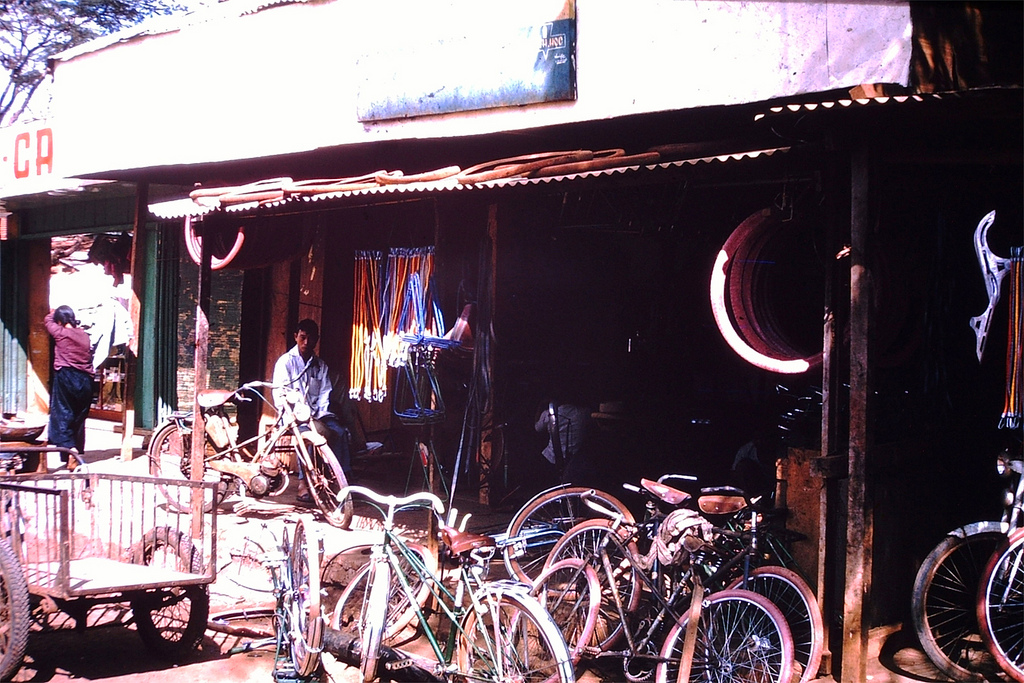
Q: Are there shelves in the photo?
A: No, there are no shelves.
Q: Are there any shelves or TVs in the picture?
A: No, there are no shelves or tvs.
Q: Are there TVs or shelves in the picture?
A: No, there are no shelves or tvs.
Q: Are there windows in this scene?
A: Yes, there is a window.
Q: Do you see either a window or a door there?
A: Yes, there is a window.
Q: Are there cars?
A: No, there are no cars.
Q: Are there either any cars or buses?
A: No, there are no cars or buses.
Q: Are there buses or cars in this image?
A: No, there are no cars or buses.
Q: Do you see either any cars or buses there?
A: No, there are no cars or buses.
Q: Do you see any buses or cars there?
A: No, there are no cars or buses.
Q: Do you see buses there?
A: No, there are no buses.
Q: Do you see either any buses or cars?
A: No, there are no buses or cars.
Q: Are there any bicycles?
A: Yes, there is a bicycle.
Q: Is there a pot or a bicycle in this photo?
A: Yes, there is a bicycle.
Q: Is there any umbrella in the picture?
A: No, there are no umbrellas.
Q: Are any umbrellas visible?
A: No, there are no umbrellas.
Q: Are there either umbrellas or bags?
A: No, there are no umbrellas or bags.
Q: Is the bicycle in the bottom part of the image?
A: Yes, the bicycle is in the bottom of the image.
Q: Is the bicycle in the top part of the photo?
A: No, the bicycle is in the bottom of the image.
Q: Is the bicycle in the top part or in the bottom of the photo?
A: The bicycle is in the bottom of the image.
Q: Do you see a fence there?
A: No, there are no fences.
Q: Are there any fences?
A: No, there are no fences.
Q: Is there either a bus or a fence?
A: No, there are no fences or buses.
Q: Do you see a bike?
A: Yes, there is a bike.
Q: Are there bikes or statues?
A: Yes, there is a bike.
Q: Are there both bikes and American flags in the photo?
A: No, there is a bike but no American flags.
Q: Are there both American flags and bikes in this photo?
A: No, there is a bike but no American flags.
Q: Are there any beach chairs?
A: No, there are no beach chairs.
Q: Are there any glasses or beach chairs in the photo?
A: No, there are no beach chairs or glasses.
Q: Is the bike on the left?
A: Yes, the bike is on the left of the image.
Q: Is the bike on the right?
A: No, the bike is on the left of the image.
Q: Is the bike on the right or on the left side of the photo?
A: The bike is on the left of the image.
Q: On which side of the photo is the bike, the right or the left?
A: The bike is on the left of the image.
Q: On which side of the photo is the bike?
A: The bike is on the left of the image.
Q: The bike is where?
A: The bike is on the side walk.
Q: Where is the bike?
A: The bike is on the sidewalk.